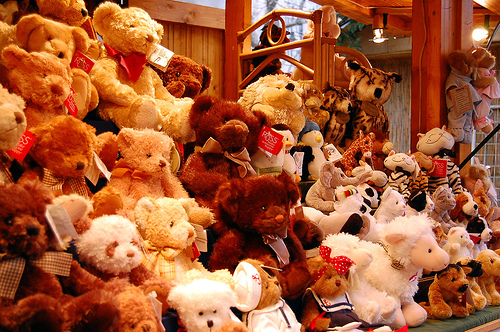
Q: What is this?
A: A retail shop.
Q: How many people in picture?
A: None.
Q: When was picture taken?
A: During daylight.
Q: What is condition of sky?
A: Clear.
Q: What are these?
A: Stuffed animals.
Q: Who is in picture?
A: No one.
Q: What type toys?
A: Stuffed bears.